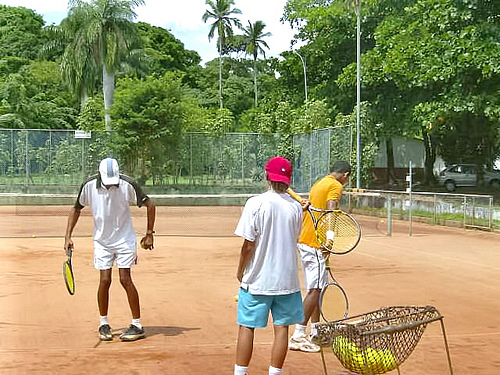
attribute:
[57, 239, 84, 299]
tennis racket — black, yellow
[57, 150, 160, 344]
player — male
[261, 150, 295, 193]
cap — red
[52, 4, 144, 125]
tree — palm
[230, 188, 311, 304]
shirt — white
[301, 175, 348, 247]
shirt — yellow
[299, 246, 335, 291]
short — white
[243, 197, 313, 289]
cap — red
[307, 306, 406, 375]
ball — yellow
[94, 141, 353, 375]
people — three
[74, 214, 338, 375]
people — three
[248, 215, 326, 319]
shirt — white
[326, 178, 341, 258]
shirt — orange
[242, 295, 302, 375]
shorts — blue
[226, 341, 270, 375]
socks — white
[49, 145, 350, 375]
people — three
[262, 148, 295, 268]
hat — red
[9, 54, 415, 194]
leaves — green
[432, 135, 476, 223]
car — gray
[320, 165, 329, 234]
shirt — yellow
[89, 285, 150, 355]
socks — white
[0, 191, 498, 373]
court — tennis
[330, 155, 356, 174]
hair — black